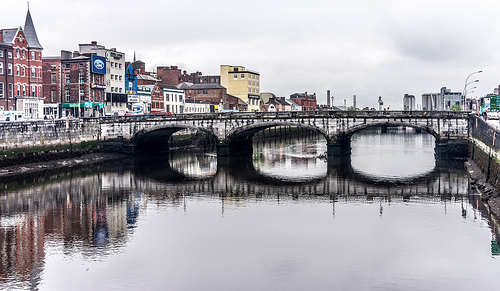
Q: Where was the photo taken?
A: It was taken at the river.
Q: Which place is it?
A: It is a river.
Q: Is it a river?
A: Yes, it is a river.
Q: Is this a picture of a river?
A: Yes, it is showing a river.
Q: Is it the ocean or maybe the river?
A: It is the river.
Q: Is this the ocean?
A: No, it is the river.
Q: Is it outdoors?
A: Yes, it is outdoors.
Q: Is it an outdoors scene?
A: Yes, it is outdoors.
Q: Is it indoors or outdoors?
A: It is outdoors.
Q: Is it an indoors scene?
A: No, it is outdoors.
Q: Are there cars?
A: No, there are no cars.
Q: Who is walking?
A: The people are walking.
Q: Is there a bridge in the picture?
A: Yes, there is a bridge.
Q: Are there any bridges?
A: Yes, there is a bridge.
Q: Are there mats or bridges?
A: Yes, there is a bridge.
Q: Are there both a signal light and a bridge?
A: No, there is a bridge but no traffic lights.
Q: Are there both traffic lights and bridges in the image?
A: No, there is a bridge but no traffic lights.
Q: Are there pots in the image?
A: No, there are no pots.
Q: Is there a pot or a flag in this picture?
A: No, there are no pots or flags.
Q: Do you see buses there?
A: No, there are no buses.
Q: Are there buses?
A: No, there are no buses.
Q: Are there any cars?
A: No, there are no cars.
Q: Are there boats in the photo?
A: No, there are no boats.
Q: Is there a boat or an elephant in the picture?
A: No, there are no boats or elephants.